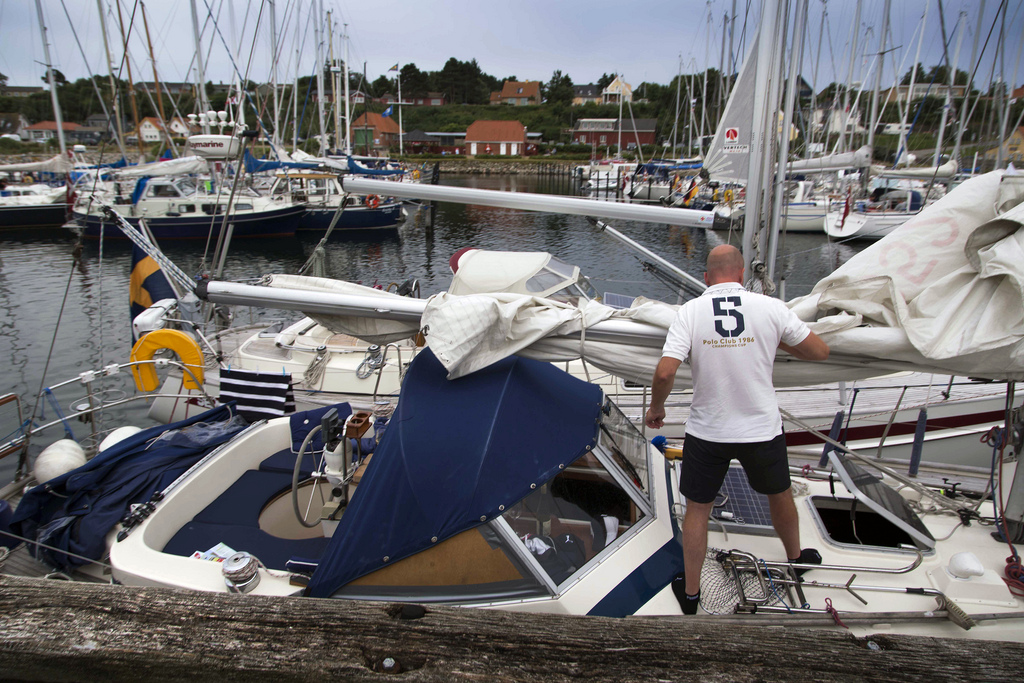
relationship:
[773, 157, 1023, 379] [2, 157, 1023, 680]
sail on boat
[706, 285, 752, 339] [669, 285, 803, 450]
5 on shirt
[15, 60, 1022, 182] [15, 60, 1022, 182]
buildings on shore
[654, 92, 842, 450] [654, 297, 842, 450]
man wearing shirt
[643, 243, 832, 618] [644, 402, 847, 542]
man wearing shorts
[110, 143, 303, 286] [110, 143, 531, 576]
boat in dock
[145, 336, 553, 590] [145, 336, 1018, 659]
boat in dock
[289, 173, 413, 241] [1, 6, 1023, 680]
boat in dock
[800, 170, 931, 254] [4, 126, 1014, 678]
boat in dock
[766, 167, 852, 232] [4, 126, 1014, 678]
boat in dock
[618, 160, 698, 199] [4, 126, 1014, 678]
boat in dock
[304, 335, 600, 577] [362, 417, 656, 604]
cover over windshield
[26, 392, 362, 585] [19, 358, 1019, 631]
interior of boat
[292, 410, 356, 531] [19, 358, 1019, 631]
steering wheel in boat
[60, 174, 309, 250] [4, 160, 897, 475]
boat sitting in body of water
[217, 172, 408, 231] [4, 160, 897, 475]
boat sitting in body of water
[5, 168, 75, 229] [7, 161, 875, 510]
boat sitting in body of water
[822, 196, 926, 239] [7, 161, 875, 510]
boat sitting in body of water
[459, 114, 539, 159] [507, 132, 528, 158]
building with window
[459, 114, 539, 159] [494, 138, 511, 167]
building with window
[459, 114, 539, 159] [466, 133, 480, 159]
building with window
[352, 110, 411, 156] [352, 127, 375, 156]
building with door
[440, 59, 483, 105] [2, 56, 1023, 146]
trees sitting on hill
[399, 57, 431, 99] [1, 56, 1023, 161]
tree sitting on hill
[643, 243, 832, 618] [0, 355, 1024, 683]
man standing on boat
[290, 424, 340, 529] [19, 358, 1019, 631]
steering wheel on boat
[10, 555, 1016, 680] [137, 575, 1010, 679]
wall on side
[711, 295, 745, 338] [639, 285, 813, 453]
5 on shirt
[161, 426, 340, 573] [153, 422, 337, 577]
blue cushions on seats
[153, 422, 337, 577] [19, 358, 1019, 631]
seats of boat